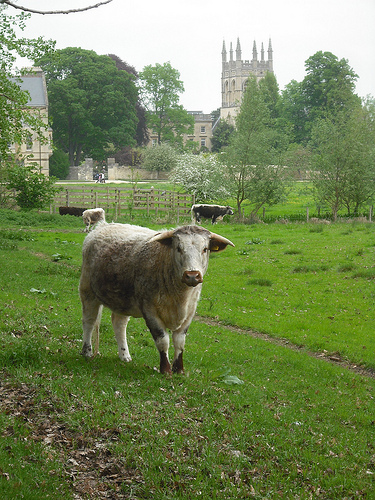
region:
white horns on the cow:
[210, 227, 234, 248]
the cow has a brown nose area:
[180, 270, 201, 286]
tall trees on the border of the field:
[232, 75, 370, 220]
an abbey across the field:
[174, 38, 242, 153]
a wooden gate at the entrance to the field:
[58, 184, 193, 225]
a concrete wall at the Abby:
[70, 156, 140, 180]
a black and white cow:
[190, 203, 235, 225]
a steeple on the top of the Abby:
[234, 35, 241, 61]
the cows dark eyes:
[201, 246, 208, 255]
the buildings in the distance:
[1, 37, 274, 182]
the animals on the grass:
[58, 203, 234, 376]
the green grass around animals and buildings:
[0, 178, 374, 498]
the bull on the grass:
[78, 219, 234, 380]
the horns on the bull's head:
[145, 229, 235, 247]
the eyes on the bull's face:
[176, 245, 206, 251]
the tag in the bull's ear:
[210, 245, 218, 250]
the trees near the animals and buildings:
[0, 0, 373, 221]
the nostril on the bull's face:
[184, 273, 200, 279]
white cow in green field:
[67, 211, 219, 381]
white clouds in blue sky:
[116, 12, 170, 32]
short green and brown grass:
[248, 355, 279, 404]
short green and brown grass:
[301, 295, 328, 317]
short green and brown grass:
[211, 395, 245, 416]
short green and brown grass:
[277, 419, 325, 446]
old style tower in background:
[219, 35, 276, 128]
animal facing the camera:
[81, 218, 233, 369]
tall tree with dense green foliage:
[43, 46, 130, 163]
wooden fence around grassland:
[48, 181, 191, 212]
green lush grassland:
[244, 227, 370, 325]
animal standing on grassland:
[78, 220, 236, 370]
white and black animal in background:
[190, 202, 233, 223]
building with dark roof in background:
[0, 70, 49, 193]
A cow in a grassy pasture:
[70, 218, 238, 387]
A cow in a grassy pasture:
[67, 219, 240, 380]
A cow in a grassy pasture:
[75, 215, 238, 380]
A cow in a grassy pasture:
[74, 217, 238, 387]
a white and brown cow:
[72, 215, 230, 378]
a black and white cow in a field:
[190, 199, 240, 232]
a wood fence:
[98, 181, 190, 223]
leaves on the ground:
[22, 380, 160, 465]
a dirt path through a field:
[247, 322, 359, 376]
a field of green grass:
[251, 217, 373, 360]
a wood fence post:
[304, 205, 310, 224]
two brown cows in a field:
[58, 199, 84, 218]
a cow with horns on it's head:
[149, 225, 243, 251]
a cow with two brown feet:
[155, 348, 185, 375]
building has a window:
[200, 125, 204, 132]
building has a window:
[200, 136, 205, 145]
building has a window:
[232, 80, 234, 89]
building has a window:
[225, 81, 227, 89]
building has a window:
[226, 94, 229, 104]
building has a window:
[200, 137, 205, 143]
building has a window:
[186, 137, 193, 142]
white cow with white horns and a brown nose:
[147, 227, 233, 288]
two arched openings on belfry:
[222, 64, 240, 109]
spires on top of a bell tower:
[219, 35, 273, 64]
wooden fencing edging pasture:
[35, 184, 195, 216]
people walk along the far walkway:
[92, 170, 108, 182]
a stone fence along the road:
[58, 163, 317, 183]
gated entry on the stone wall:
[93, 159, 106, 180]